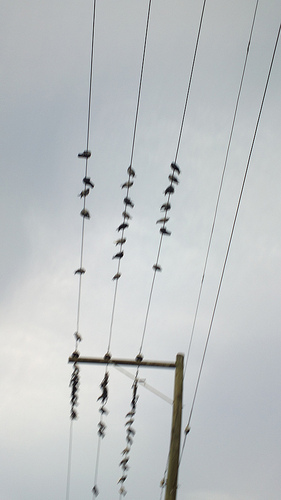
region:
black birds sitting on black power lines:
[58, 138, 189, 283]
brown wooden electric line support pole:
[65, 350, 187, 498]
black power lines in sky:
[87, 0, 269, 145]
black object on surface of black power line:
[182, 422, 194, 439]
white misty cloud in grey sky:
[6, 264, 56, 350]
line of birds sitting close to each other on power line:
[62, 362, 84, 420]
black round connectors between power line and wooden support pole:
[68, 347, 84, 360]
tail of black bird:
[93, 393, 102, 403]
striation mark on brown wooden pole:
[173, 404, 180, 431]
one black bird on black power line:
[65, 245, 93, 295]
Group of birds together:
[65, 140, 240, 297]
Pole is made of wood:
[142, 397, 188, 482]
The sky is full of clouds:
[234, 401, 277, 465]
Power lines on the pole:
[59, 408, 113, 496]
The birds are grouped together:
[103, 390, 153, 461]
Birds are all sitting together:
[46, 365, 165, 498]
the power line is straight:
[55, 460, 72, 488]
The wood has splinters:
[164, 368, 190, 412]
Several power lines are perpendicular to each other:
[81, 18, 274, 105]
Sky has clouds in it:
[33, 259, 58, 324]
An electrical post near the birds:
[70, 352, 180, 499]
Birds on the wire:
[119, 409, 135, 495]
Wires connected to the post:
[71, 362, 170, 498]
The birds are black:
[71, 368, 79, 419]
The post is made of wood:
[68, 354, 184, 498]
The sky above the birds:
[0, 0, 280, 496]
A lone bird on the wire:
[185, 424, 190, 434]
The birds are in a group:
[117, 395, 137, 494]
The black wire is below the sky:
[66, 0, 280, 496]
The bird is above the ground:
[75, 268, 86, 274]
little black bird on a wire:
[74, 144, 94, 161]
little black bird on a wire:
[151, 259, 161, 274]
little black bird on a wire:
[88, 483, 100, 495]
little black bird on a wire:
[168, 153, 181, 173]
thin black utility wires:
[58, 1, 277, 498]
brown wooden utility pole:
[65, 344, 188, 497]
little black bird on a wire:
[108, 248, 130, 262]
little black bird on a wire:
[120, 444, 134, 453]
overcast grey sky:
[0, 0, 280, 499]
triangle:
[109, 358, 180, 404]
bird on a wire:
[73, 149, 97, 163]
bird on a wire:
[103, 355, 109, 363]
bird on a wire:
[117, 475, 127, 485]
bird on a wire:
[115, 456, 128, 466]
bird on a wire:
[125, 429, 137, 440]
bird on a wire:
[115, 471, 130, 479]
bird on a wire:
[113, 475, 126, 482]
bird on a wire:
[117, 487, 134, 496]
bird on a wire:
[86, 483, 106, 499]